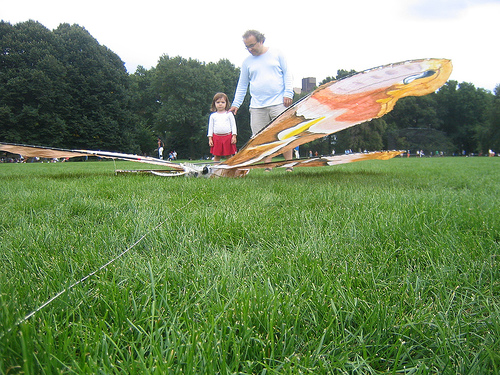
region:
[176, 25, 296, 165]
A man and small child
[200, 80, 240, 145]
Small girl is wearing a white shirt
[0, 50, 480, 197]
A kite is in the foreground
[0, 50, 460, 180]
The kite is in the shape of a moth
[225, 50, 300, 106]
Man is wearing a light blue shirt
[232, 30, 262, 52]
Man is wearing glasses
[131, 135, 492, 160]
People are in the background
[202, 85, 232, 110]
Young girl has brown colored hair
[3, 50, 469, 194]
Kite is on the grass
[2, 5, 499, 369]
Photo was taken outdoors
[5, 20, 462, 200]
man and child standing in grass before large kite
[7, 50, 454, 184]
large insect shaped kite on green grass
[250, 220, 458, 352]
patch of green grass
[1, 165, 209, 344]
string attached to kite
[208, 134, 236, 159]
red fabric shorts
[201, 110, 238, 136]
white long sleeve shirt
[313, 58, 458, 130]
orange and yellow design on wing of kite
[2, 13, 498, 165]
large trees bordering green field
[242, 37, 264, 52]
pair of glasses on face of man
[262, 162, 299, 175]
feet in brown sandals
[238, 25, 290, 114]
this is a man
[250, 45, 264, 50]
the man is light skinned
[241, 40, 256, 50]
this is a spectacle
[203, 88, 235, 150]
this is a girl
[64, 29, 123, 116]
this is a tree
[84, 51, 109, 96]
the leaves are green in color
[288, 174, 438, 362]
this is a grass area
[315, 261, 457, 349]
the grass is green in color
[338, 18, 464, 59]
this is the sky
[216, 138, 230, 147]
this is a skirt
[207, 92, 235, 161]
young little girl standing up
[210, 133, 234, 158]
girl's short knee high red skirt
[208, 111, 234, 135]
girl's white long sleeved shirt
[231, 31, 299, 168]
man standing up with hand on girl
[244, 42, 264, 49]
man's glasses on his face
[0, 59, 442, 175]
large butterfly kit in orange and yellow and white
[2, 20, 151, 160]
tall dark green tree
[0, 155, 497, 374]
short green grass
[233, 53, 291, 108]
man's light blue shirt he is wearing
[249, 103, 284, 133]
man's khaki shorts that he has on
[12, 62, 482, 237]
a large fancy kite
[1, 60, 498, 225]
the kite looks like a butterfly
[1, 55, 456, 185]
the kite is on the grass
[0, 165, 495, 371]
the grass is very bright and green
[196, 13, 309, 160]
a little girl with her dad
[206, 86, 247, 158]
the little girl is wearing a red skirt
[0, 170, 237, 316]
the kite's string is in the grass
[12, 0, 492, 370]
they are at a park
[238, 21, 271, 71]
he is wearing glasses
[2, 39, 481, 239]
the kite is colorful